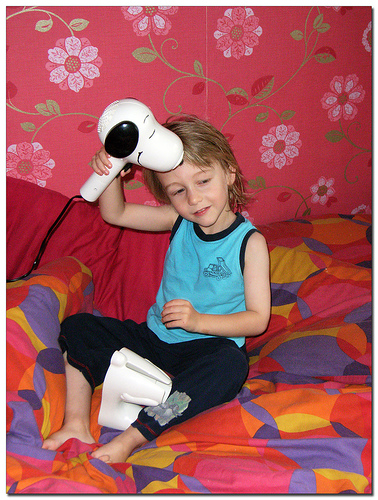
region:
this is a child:
[132, 143, 264, 389]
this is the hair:
[185, 120, 226, 151]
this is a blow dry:
[102, 103, 180, 173]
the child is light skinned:
[248, 248, 266, 272]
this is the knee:
[202, 341, 245, 378]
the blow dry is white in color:
[144, 131, 175, 161]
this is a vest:
[185, 238, 236, 295]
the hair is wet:
[186, 123, 221, 155]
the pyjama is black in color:
[197, 344, 236, 381]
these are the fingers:
[158, 307, 206, 337]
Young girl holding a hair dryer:
[78, 95, 261, 269]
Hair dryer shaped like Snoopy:
[76, 91, 187, 206]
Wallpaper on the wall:
[7, 8, 372, 225]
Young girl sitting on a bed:
[8, 116, 371, 494]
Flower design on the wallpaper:
[40, 32, 105, 96]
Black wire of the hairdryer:
[7, 192, 82, 285]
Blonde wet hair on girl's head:
[140, 108, 256, 212]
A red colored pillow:
[7, 165, 178, 323]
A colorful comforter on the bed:
[9, 209, 371, 491]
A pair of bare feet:
[40, 415, 144, 466]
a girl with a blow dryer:
[42, 93, 320, 358]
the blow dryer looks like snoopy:
[67, 84, 191, 212]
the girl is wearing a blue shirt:
[135, 216, 279, 349]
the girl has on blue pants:
[56, 312, 244, 439]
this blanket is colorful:
[204, 402, 360, 488]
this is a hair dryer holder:
[86, 345, 175, 429]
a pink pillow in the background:
[264, 111, 368, 211]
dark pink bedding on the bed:
[28, 204, 164, 304]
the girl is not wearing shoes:
[44, 411, 139, 485]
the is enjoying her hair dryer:
[48, 109, 256, 261]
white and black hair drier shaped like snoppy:
[77, 97, 185, 199]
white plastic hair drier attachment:
[95, 346, 171, 429]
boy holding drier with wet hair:
[81, 97, 246, 227]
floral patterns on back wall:
[324, 70, 364, 185]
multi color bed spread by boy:
[270, 266, 362, 385]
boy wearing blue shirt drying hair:
[39, 96, 272, 461]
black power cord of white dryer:
[45, 193, 82, 233]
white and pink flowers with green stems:
[45, 13, 99, 87]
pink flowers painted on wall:
[257, 122, 301, 167]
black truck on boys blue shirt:
[202, 255, 231, 280]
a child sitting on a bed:
[20, 123, 321, 468]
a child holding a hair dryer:
[90, 96, 274, 328]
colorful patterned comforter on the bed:
[278, 351, 366, 466]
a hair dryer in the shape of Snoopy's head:
[75, 102, 175, 208]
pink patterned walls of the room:
[262, 53, 346, 161]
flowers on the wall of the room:
[219, 6, 310, 156]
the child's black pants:
[74, 311, 245, 433]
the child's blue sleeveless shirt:
[143, 217, 271, 349]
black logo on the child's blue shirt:
[198, 252, 237, 286]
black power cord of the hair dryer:
[8, 193, 81, 283]